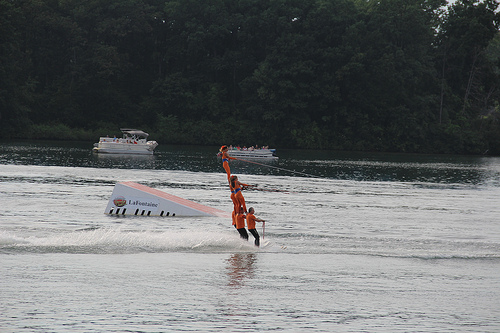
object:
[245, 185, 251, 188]
hand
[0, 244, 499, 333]
waters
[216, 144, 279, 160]
boat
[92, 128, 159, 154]
boat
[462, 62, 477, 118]
trunk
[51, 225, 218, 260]
water splashes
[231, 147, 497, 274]
rope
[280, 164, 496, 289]
waves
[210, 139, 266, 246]
people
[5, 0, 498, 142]
woods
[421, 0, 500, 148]
tree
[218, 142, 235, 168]
person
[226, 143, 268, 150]
people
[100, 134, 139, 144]
people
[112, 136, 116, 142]
person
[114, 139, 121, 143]
person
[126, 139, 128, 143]
person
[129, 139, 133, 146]
person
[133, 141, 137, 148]
person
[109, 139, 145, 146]
bunch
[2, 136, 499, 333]
body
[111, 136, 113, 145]
person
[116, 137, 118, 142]
person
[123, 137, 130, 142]
person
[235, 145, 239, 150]
person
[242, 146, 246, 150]
person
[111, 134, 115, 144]
person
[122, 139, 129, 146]
person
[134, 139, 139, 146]
person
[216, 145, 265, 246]
group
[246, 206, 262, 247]
man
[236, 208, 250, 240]
man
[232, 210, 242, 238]
man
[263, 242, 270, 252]
ski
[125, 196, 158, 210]
word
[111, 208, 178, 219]
word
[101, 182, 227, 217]
ramp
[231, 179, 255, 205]
person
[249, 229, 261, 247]
black pants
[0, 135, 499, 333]
lake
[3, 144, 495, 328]
water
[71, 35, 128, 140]
tree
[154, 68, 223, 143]
tree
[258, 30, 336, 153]
tree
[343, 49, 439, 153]
tree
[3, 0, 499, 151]
background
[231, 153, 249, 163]
handle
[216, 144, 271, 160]
group